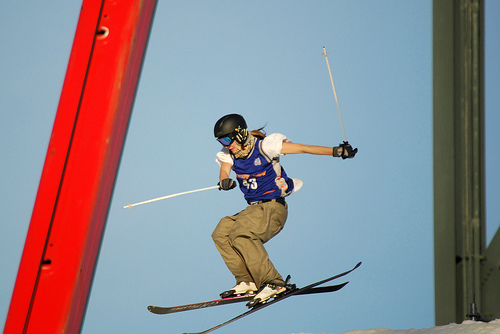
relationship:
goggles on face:
[221, 135, 241, 147] [221, 132, 246, 154]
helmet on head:
[197, 97, 259, 135] [212, 111, 253, 159]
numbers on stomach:
[242, 175, 259, 190] [235, 162, 293, 203]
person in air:
[212, 113, 359, 306] [7, 4, 494, 326]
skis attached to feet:
[140, 283, 350, 311] [214, 266, 288, 305]